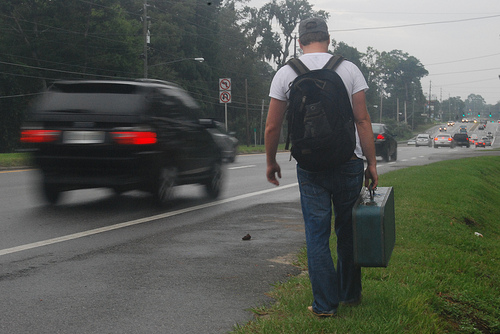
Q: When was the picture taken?
A: During the day.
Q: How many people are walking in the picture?
A: One.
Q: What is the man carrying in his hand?
A: Luggage.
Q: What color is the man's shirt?
A: White.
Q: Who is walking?
A: A man.